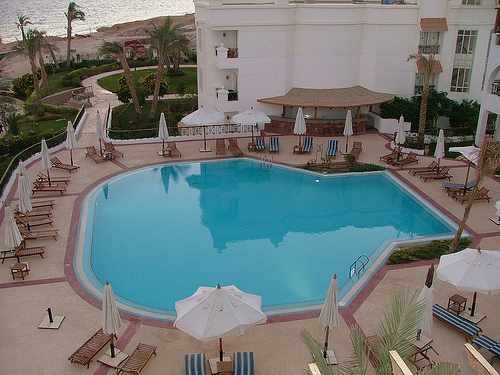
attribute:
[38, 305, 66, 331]
umbrella holder — black , white 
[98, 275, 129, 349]
umbrella — closed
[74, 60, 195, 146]
walking path — grey 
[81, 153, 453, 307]
swimming pool — large 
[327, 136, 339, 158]
chairs — blue , white 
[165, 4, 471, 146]
building — white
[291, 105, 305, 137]
umbrella — folded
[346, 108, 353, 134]
umbrella — folded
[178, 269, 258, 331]
umbrella — folded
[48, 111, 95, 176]
umbrella — folded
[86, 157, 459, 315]
pool — blue 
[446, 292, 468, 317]
table — Brown , small 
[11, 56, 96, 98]
bushes — green , yellow 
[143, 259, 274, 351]
umbrella — white 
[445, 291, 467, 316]
table — wooden , small 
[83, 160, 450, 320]
water — Blue 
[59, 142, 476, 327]
swimming pool — large 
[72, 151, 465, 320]
water — light blue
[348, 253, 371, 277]
pool ladder — silver 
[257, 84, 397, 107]
awning — brown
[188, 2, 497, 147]
building — white 